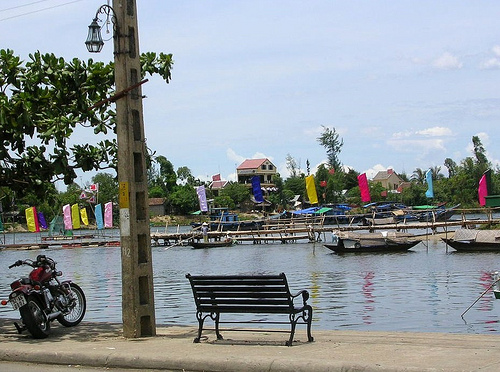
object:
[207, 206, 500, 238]
pier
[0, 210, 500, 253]
dock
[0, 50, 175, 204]
tree branch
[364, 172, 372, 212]
pole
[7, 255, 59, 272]
handle bars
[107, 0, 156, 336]
pole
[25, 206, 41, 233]
flag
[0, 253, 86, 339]
bike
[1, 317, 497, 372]
concrete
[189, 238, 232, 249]
boat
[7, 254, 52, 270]
bars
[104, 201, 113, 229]
banner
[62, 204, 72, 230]
banner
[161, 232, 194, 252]
stick/water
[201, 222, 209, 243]
man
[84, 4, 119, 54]
lamp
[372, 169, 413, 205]
house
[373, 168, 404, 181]
roof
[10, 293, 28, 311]
license plate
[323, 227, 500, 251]
boats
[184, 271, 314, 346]
bench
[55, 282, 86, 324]
tire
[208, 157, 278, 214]
house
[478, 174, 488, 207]
banner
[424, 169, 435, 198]
banner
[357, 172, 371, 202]
banner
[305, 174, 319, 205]
banner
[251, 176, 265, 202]
banner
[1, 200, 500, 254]
docking area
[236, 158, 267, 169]
roof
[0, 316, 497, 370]
sidewalk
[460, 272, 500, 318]
stick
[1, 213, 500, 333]
water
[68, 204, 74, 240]
pole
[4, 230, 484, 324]
area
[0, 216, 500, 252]
pier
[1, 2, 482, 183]
sky